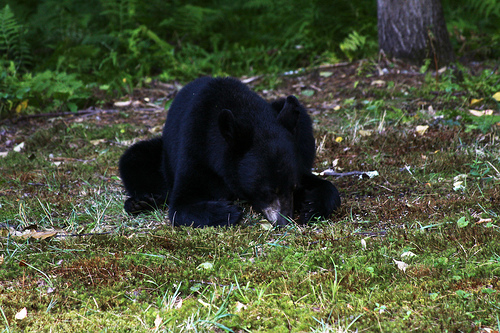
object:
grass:
[2, 0, 500, 332]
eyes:
[250, 175, 302, 193]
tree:
[377, 1, 453, 66]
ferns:
[1, 3, 498, 118]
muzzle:
[261, 194, 293, 228]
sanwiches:
[0, 223, 59, 243]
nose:
[276, 212, 294, 232]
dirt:
[282, 61, 426, 93]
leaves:
[301, 89, 315, 96]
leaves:
[433, 78, 461, 94]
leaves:
[457, 216, 469, 229]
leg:
[117, 136, 165, 218]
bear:
[117, 76, 341, 227]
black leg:
[276, 95, 317, 168]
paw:
[123, 196, 155, 217]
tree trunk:
[379, 1, 454, 65]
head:
[217, 95, 306, 230]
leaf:
[5, 226, 59, 242]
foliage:
[1, 2, 498, 127]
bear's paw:
[168, 201, 243, 229]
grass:
[0, 19, 498, 330]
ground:
[2, 56, 500, 331]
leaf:
[453, 173, 468, 191]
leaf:
[89, 139, 105, 146]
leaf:
[371, 80, 386, 88]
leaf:
[392, 250, 417, 273]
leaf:
[14, 304, 31, 321]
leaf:
[233, 301, 247, 314]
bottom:
[371, 29, 461, 66]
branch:
[1, 211, 106, 258]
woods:
[4, 0, 497, 333]